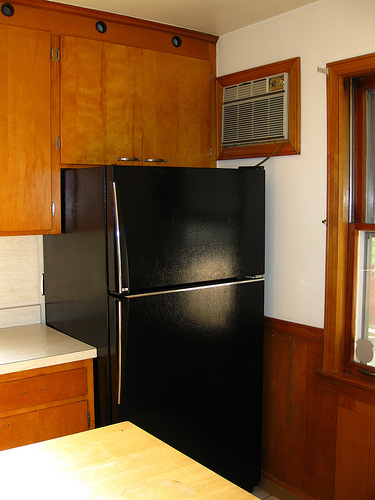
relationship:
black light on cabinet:
[171, 33, 182, 48] [0, 9, 221, 234]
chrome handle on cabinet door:
[119, 155, 141, 162] [59, 34, 142, 164]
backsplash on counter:
[0, 303, 42, 328] [0, 324, 98, 374]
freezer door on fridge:
[106, 161, 269, 291] [43, 164, 265, 495]